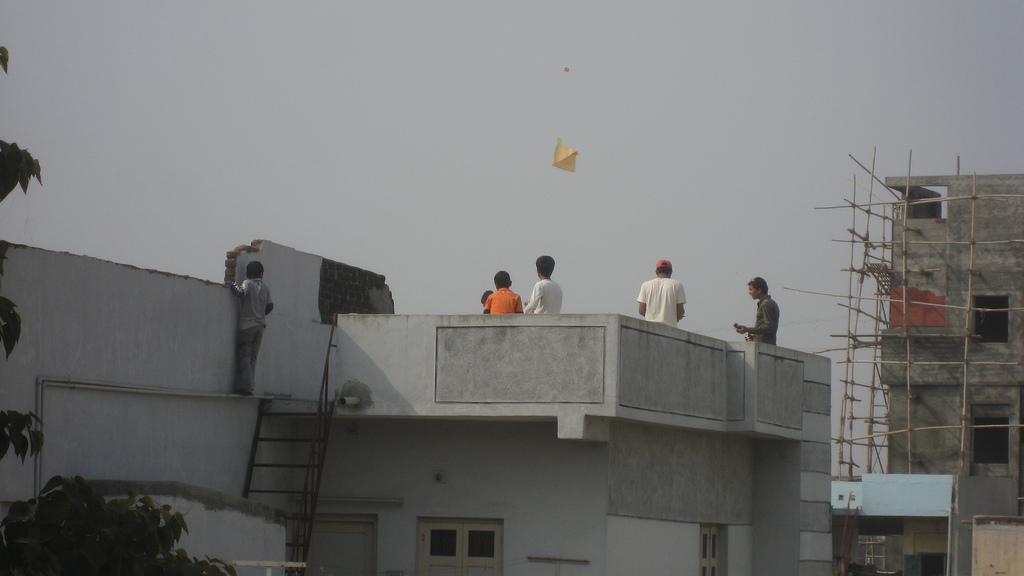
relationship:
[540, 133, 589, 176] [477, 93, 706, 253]
kite in sky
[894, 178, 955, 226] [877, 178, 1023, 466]
window on a building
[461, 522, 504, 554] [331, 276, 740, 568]
window on a building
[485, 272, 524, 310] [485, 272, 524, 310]
person wearing a shirt